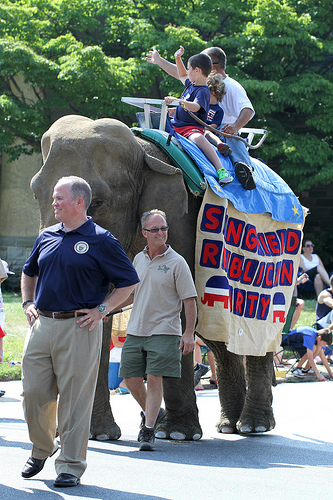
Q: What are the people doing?
A: Riding an elephant.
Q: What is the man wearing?
A: Blue polo shirt.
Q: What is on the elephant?
A: A sign.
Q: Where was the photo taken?
A: Outside somewhere.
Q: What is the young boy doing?
A: Waving to a crowd.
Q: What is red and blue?
A: The sign.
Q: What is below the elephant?
A: Shadow.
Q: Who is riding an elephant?
A: A group of three people.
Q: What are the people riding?
A: An elephant.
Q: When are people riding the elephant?
A: During daylight hours.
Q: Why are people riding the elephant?
A: For enjoyment.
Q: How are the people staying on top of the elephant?
A: They are roped in.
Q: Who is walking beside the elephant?
A: A man.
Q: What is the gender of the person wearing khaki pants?
A: Male.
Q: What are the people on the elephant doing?
A: Waving.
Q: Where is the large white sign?
A: Hanging on the elephant.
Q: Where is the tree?
A: Behind the people.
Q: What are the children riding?
A: An elephant.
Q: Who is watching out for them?
A: Two wildlife park employees.